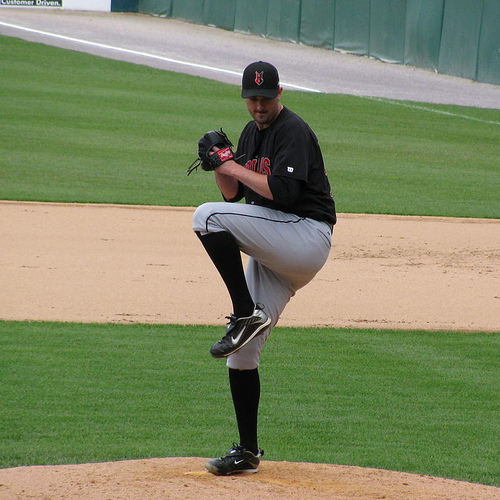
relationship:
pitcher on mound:
[97, 17, 389, 497] [113, 388, 336, 497]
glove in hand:
[164, 98, 267, 244] [187, 112, 269, 225]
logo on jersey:
[224, 147, 287, 183] [218, 84, 340, 225]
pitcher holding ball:
[97, 17, 389, 497] [202, 132, 244, 178]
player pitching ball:
[97, 17, 389, 497] [202, 132, 244, 178]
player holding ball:
[97, 17, 389, 497] [202, 132, 244, 178]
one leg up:
[181, 205, 290, 393] [186, 232, 338, 406]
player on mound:
[176, 161, 393, 494] [113, 388, 336, 497]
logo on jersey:
[224, 147, 287, 183] [177, 84, 350, 246]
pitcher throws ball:
[97, 17, 389, 497] [202, 132, 244, 178]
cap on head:
[220, 41, 291, 112] [206, 41, 295, 161]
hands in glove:
[187, 112, 269, 225] [164, 98, 267, 244]